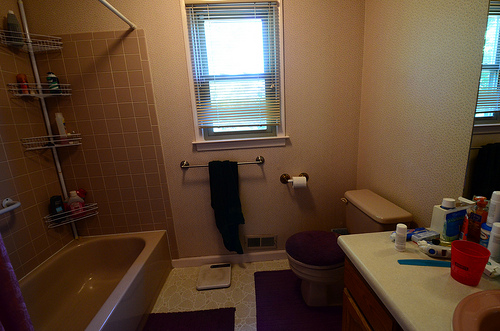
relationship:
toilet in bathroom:
[285, 184, 414, 316] [0, 0, 498, 329]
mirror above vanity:
[462, 0, 500, 202] [336, 227, 498, 329]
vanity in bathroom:
[336, 227, 498, 329] [0, 0, 498, 329]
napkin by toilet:
[292, 177, 307, 189] [285, 184, 414, 316]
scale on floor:
[196, 263, 231, 291] [145, 255, 340, 329]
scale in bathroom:
[196, 263, 231, 291] [0, 0, 498, 329]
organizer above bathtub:
[3, 6, 105, 238] [6, 224, 179, 329]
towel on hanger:
[208, 160, 245, 254] [180, 156, 265, 170]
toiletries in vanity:
[388, 188, 498, 287] [336, 227, 498, 329]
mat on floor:
[142, 307, 236, 331] [145, 255, 340, 329]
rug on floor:
[253, 269, 343, 331] [145, 255, 340, 329]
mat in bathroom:
[142, 307, 236, 331] [0, 0, 498, 329]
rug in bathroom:
[253, 269, 343, 331] [0, 0, 498, 329]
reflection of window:
[484, 5, 497, 128] [192, 8, 282, 138]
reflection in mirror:
[484, 5, 497, 128] [477, 8, 499, 195]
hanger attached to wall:
[176, 154, 266, 173] [6, 2, 487, 277]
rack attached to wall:
[1, 0, 101, 241] [1, 27, 180, 280]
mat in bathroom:
[153, 306, 296, 329] [0, 0, 500, 331]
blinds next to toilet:
[180, 0, 286, 140] [285, 184, 414, 316]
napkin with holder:
[291, 173, 311, 188] [280, 172, 309, 183]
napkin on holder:
[292, 177, 307, 189] [278, 171, 310, 188]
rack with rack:
[0, 30, 98, 229] [0, 30, 98, 229]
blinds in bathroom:
[180, 0, 286, 140] [65, 22, 448, 329]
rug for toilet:
[253, 269, 343, 331] [257, 220, 341, 327]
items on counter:
[418, 189, 488, 286] [334, 213, 499, 329]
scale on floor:
[196, 261, 229, 287] [169, 270, 251, 329]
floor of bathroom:
[169, 270, 251, 329] [21, 14, 430, 314]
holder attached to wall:
[276, 171, 327, 193] [152, 4, 497, 278]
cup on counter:
[448, 237, 496, 289] [334, 213, 499, 329]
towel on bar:
[199, 154, 255, 270] [159, 142, 275, 178]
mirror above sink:
[462, 0, 498, 206] [453, 289, 495, 329]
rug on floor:
[253, 270, 367, 330] [145, 255, 340, 329]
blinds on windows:
[193, 11, 278, 129] [174, 10, 284, 121]